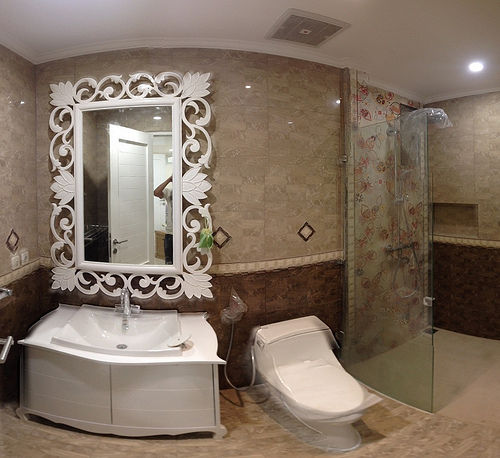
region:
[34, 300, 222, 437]
clean white bathroom sink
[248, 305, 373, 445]
A toilet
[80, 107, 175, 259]
A mirror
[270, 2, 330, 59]
a bathroom vent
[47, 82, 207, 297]
a white frame around the mirror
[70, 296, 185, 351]
A white sink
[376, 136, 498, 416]
A walk in shower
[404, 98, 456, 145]
a shower head in the shower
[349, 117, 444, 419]
a glass partition separating the shower and the main bathroom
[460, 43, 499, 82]
a light in the shower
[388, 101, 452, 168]
a plastic bag over the shower head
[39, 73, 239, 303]
mirror within ornate picture frame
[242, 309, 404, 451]
modern looking toilet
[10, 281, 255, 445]
white sink and vanity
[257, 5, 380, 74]
recessed ceiling fan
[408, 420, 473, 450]
simulated marble flooring in a bathroom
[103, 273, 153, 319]
chrome plated water faucet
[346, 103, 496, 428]
shower area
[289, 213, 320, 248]
simulated marble ornament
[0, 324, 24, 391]
handicap access railing in bathroom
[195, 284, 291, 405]
water line cable in bathroom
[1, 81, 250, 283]
mirror on the wall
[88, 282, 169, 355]
sink below the mirror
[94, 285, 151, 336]
faucet of the sink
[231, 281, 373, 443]
toilet next to sink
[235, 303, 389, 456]
white object on ground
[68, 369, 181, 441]
bottom part of sink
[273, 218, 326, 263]
diamond shaped wall design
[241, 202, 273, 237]
wall next to mirror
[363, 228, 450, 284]
glass next to wall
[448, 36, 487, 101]
light on the ceiling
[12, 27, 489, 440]
This is a private bathroom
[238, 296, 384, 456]
There is a white toilet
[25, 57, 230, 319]
There is a large white mirror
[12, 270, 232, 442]
There is a large white sink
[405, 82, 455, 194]
The shower head has plastic over it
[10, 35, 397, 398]
There is brown tile on the wall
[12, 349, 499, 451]
There is brown tile on the floor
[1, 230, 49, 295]
There are two white outlets on the wall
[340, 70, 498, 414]
There is a stand up shower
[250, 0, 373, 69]
There is a vent on the ceiling